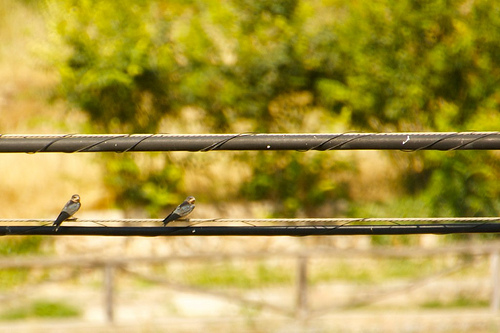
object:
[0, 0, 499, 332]
green vegetation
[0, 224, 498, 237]
cable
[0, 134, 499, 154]
cable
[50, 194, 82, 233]
perched birds